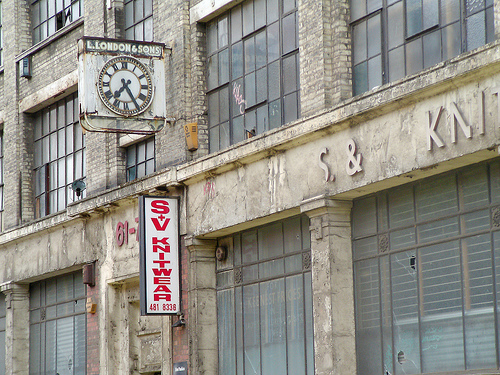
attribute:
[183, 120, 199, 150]
container — yellow, small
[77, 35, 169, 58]
rusty sign — L.London & Sons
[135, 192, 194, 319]
sign — rectangular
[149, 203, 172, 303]
lettering — red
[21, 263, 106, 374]
windows — glass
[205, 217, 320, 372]
windows — glass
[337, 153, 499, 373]
windows — glass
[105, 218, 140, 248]
sign — red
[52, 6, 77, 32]
broken window — third floor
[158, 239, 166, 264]
letters — red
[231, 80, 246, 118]
letters — red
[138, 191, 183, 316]
sign — white, red, small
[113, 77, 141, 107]
hands — black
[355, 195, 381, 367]
window — glass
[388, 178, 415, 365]
window — glass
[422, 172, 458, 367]
window — glass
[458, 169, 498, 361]
window — glass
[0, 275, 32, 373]
column — dusty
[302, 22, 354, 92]
bricks — dirty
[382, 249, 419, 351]
window — lower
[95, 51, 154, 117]
clock — worn out, old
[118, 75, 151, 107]
hands — black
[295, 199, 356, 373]
column — dusty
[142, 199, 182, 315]
sign — white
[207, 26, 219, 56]
window — glass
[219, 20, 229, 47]
window — glass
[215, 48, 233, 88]
window — glass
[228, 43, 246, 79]
window — glass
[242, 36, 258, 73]
window — glass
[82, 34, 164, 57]
sign — L. London & Sons